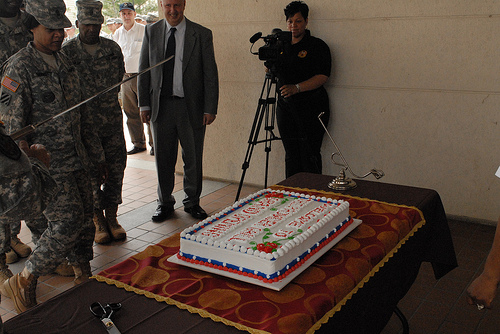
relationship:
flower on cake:
[254, 240, 276, 255] [171, 176, 363, 283]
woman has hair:
[259, 1, 337, 182] [281, 2, 311, 18]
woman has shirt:
[259, 1, 337, 182] [268, 33, 333, 106]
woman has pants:
[259, 1, 337, 182] [266, 87, 335, 173]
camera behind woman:
[224, 31, 311, 203] [259, 1, 337, 182]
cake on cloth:
[171, 176, 363, 283] [99, 177, 431, 332]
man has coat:
[132, 3, 229, 230] [134, 20, 221, 129]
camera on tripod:
[224, 31, 311, 203] [229, 72, 316, 201]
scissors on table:
[83, 295, 125, 332] [5, 162, 470, 331]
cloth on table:
[99, 177, 431, 332] [5, 162, 470, 331]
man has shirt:
[108, 5, 157, 155] [113, 24, 149, 76]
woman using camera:
[259, 1, 337, 182] [224, 31, 311, 203]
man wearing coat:
[132, 3, 229, 230] [134, 20, 221, 129]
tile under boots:
[127, 229, 150, 238] [90, 202, 140, 244]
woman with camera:
[259, 1, 337, 182] [224, 31, 311, 203]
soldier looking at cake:
[63, 0, 134, 248] [171, 176, 363, 283]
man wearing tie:
[132, 3, 229, 230] [154, 27, 183, 101]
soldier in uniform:
[63, 0, 134, 248] [64, 37, 132, 204]